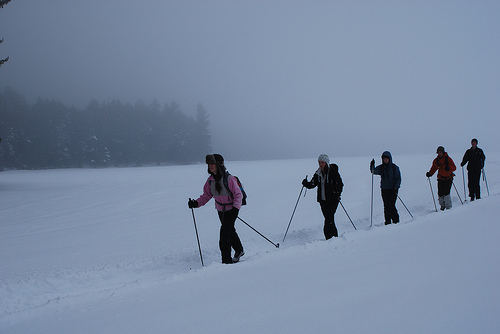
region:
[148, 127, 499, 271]
a row of skiers walking in snow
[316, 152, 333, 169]
white hat on skiers head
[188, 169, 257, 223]
a pink jacket on woman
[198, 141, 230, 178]
black hat on woman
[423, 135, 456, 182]
a red jacket on another skier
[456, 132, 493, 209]
one skier at the end of the line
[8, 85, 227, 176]
a row of trees in the distance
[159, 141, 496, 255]
all skiers have poles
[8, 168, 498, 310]
ditch in snow made by skiers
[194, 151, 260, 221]
front skier carries a backpack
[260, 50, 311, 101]
part of a cloud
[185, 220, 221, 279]
part of a hooker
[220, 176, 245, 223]
part of a jacket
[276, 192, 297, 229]
part of a hooker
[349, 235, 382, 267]
part of a snow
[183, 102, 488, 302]
Five people hiking through snow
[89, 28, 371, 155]
Dark and dismal day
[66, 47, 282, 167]
Fog in the distance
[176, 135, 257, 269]
Person hiking through the snow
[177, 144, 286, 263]
Person wearing a pink jacket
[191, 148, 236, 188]
Warm winter hat with fur around it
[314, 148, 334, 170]
White stocking cap on head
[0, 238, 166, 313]
Path in the snow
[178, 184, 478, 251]
People hiking through snow with ski poles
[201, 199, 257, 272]
Person wearing dark pants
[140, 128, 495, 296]
people walking in the snow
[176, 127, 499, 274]
people walking in the in their snowsuit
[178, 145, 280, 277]
a personal walking the snow with ski poles in each hand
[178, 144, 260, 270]
a person in pink and black pants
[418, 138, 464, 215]
a person in read and black walking in the snow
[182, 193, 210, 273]
a ski pole a person is using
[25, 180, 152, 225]
ground covered with snow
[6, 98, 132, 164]
trees with some snow on the branches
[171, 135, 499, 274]
five people walking in the snow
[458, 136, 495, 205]
a person walking in the snow with snow gear on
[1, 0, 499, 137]
fog forming behind the cross country skiers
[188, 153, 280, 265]
a cross country skier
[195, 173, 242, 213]
the cross country skier is wearing a pink jacket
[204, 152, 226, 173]
cold weather fur flyers hat and ear flaps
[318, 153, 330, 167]
a white knit cap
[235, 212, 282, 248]
cross country ski poles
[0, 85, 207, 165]
thick trees on the side of the trail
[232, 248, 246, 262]
cross country ski boots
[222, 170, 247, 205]
a back pack and shoulder strap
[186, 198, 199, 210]
the skier is wearing black ski gloves